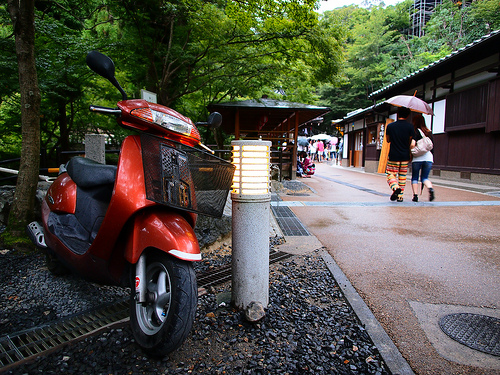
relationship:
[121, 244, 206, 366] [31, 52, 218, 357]
black tire on scooter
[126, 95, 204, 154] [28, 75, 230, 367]
headlight on scooter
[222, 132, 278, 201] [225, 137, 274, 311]
light on glowing lamp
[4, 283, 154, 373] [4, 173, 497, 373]
vent on ground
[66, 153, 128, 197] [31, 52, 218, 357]
black seat on scooter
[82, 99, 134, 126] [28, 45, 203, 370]
handlebar on motorcycle is red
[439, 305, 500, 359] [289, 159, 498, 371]
black manhole cover on street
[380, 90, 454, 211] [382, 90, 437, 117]
man and woman under brown umbrella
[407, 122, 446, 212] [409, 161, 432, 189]
woman wearing blue jeans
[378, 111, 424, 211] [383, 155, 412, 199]
man wearing pants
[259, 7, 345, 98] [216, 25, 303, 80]
leaves on branches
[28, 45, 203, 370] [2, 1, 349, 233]
motorcycle is red under trees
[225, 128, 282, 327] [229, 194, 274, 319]
glowing lamp on cyclinder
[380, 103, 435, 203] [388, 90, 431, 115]
man and woman sharing umbrella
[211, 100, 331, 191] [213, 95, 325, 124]
open structure has roof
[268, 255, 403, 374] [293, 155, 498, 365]
gravel and gratings next to walkway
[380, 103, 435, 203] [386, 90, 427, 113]
man and woman has umbrella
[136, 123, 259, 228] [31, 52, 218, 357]
black metal basket on scooter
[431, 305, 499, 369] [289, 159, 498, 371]
black manhole cover in street